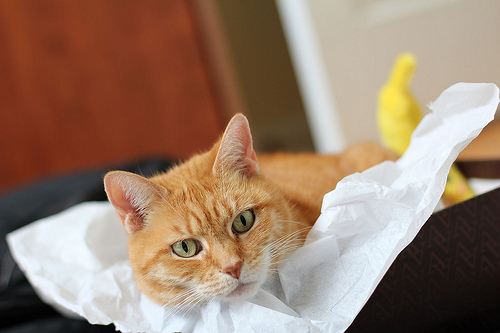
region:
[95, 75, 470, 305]
A cat is sitting on a bag.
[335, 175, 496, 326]
A bag.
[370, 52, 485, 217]
A banana shaped plush toy.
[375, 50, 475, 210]
The plush toy is yellow.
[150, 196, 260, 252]
The cat's pupils are oval shaped.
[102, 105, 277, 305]
The cat's ears are sticking up.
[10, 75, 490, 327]
The cat is on a piece of tissue paper.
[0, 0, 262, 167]
A door is in the background.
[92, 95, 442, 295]
The cat is orange and white.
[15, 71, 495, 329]
The tissue paper is white.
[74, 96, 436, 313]
An orange cat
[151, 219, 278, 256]
The cat's green eyes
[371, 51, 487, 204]
A yellow object behind the cat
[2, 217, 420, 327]
The white napkin that the cat is laying on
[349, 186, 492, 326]
Piece of furniture under the cat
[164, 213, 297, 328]
The cat's white whiskers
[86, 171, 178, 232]
One of the cat's ears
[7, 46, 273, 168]
A wooden door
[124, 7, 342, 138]
The open door way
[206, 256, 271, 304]
The cat's pink nose and mouth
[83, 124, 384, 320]
This is a cat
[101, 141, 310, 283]
The cat has green eyes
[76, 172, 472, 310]
The cat is sitting on paper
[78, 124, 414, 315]
The cat is orange and white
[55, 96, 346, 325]
The cat has whiskers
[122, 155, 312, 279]
The cats eyes are green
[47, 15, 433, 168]
The background is blurry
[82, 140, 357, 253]
The cat has two ears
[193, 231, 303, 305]
The cat has a pink nose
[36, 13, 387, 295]
There is only 1 cat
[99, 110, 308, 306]
a cute cat's face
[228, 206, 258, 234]
the left eye of a cat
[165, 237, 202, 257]
the right eye of a cat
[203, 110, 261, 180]
the left ear of a cat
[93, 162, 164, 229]
the right ear of a cat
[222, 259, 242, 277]
the nose of a cat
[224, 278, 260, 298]
a cat's mouth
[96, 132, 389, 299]
a cat with lovely fur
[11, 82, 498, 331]
a cat lying on a white paper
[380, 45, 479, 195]
a banana in a distance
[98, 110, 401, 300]
a lonely cat looking at the camera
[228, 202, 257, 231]
a cat's left eye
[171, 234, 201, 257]
a cat's right eye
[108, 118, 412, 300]
a cat lying down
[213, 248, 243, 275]
nose of a cat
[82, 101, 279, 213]
ears of a cat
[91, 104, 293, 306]
a cat's face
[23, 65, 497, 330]
a cat on white paper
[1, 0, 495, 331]
lovely picture of a cat